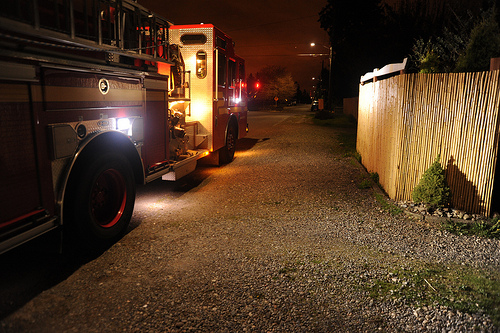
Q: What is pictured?
A: Firetruck.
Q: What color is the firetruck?
A: Red.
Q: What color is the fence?
A: Brown.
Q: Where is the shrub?
A: In front of fence.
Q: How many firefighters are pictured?
A: 0.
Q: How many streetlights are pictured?
A: 1.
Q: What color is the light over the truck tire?
A: White.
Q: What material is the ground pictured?
A: Gravel.